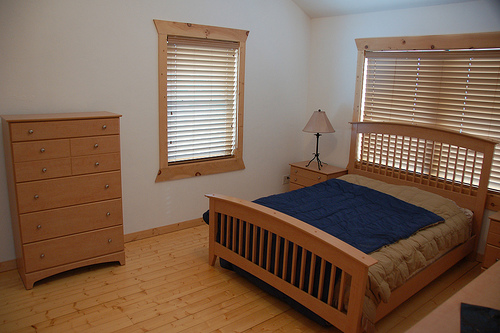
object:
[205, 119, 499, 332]
bed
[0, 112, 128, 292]
dresser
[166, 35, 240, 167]
window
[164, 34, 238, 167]
window shade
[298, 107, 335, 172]
lamp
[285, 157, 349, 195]
night stand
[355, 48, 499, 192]
window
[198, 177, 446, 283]
blanket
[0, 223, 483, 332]
floor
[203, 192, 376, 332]
foot board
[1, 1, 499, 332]
bedroom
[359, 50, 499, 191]
blinds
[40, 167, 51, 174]
knobs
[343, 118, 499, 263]
head board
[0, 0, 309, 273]
wall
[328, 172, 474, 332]
bed cover